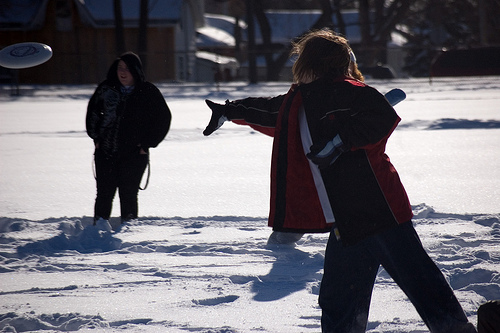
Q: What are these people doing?
A: Throwing a frisbee.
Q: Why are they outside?
A: They are playing sports.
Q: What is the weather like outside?
A: It is winter.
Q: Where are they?
A: They are outside.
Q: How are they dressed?
A: They are wearing coats.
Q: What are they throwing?
A: They are throwing a frisbee.